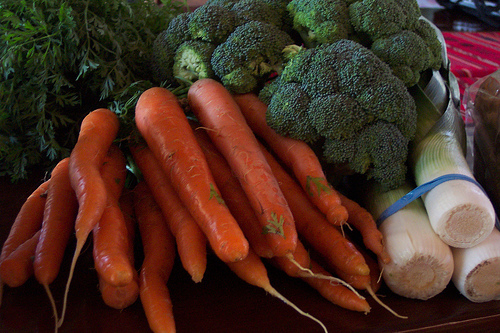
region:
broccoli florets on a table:
[156, 3, 438, 190]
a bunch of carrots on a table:
[3, 0, 388, 331]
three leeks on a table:
[351, 46, 499, 304]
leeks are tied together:
[350, 63, 499, 303]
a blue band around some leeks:
[371, 169, 498, 244]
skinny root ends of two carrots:
[36, 228, 92, 332]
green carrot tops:
[4, 3, 190, 178]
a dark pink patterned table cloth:
[437, 24, 499, 94]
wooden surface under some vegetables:
[7, 267, 498, 332]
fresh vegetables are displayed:
[3, 1, 498, 331]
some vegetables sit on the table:
[11, 8, 484, 308]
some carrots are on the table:
[8, 13, 364, 324]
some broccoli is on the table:
[193, 9, 437, 164]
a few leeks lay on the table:
[373, 73, 498, 319]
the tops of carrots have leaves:
[5, 7, 200, 140]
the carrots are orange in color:
[16, 90, 362, 318]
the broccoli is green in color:
[191, 13, 420, 147]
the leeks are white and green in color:
[373, 125, 493, 305]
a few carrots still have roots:
[276, 258, 386, 332]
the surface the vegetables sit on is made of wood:
[17, 293, 489, 330]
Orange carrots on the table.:
[2, 85, 404, 322]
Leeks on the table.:
[358, 106, 497, 304]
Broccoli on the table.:
[265, 35, 413, 190]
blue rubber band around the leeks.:
[375, 170, 486, 232]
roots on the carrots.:
[33, 233, 96, 331]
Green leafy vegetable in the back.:
[2, 2, 163, 172]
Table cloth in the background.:
[440, 27, 499, 122]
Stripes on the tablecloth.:
[440, 26, 498, 122]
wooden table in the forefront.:
[0, 259, 497, 331]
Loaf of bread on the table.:
[462, 64, 498, 207]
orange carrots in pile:
[30, 54, 247, 302]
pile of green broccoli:
[260, 33, 408, 183]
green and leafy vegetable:
[5, 5, 195, 129]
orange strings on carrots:
[227, 263, 348, 331]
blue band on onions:
[357, 178, 462, 246]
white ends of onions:
[387, 170, 477, 304]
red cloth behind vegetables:
[435, 23, 487, 121]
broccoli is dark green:
[185, 14, 426, 165]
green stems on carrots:
[58, 45, 186, 109]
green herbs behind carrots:
[5, 10, 204, 157]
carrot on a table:
[29, 73, 120, 324]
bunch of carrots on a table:
[16, 62, 394, 332]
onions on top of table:
[387, 121, 498, 298]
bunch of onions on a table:
[346, 92, 498, 303]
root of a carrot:
[255, 275, 339, 330]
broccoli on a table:
[267, 35, 419, 192]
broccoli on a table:
[210, 25, 287, 85]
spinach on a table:
[12, 26, 114, 81]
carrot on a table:
[137, 89, 261, 291]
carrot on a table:
[177, 71, 332, 283]